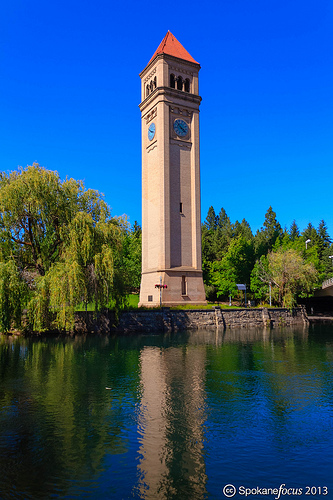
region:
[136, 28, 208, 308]
stone clock tower next to water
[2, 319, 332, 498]
water next to clock tower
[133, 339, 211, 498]
reflection of the clock tower in the water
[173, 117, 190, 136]
clock face on clock tower showing time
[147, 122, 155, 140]
clock on clock tower showing time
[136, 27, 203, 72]
red roof of the clock tower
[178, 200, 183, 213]
small window in stone clock tower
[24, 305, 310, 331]
stone wall at the edge of the water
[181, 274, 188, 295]
small door in clock tower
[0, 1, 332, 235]
clear blue sky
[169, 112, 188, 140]
A clock on the tower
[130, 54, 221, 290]
A tower in front of the water.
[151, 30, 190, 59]
The roof of the tower.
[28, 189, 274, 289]
Trees behind the tower.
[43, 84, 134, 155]
The sky is clear and blue.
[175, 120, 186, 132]
The hands on the clock is black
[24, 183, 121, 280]
The trees are green.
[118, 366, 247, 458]
A reflection of the tower in the water.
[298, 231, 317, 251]
A light pole sticking through the trees.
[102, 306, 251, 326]
A stone wall by the tower.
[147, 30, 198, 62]
Red pointy roof on a tall thin tower.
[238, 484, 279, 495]
The word Spokane before the word focus.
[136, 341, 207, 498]
A tall brown tower reflection in the water.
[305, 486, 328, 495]
The year 2013.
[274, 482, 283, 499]
The white letter F in focus.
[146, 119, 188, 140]
Two clocks on the top of a tower.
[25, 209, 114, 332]
A green willow tree to the left of a tower.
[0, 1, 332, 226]
Bright blue sky all around a tower.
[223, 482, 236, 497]
A round white circle with CC inside.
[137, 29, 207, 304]
A brown tower with red roof and two clocks.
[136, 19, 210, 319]
clock tower on side of river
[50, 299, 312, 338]
retaining wall on side of river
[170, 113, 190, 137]
clock on clock tower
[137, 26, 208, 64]
roof on clock tower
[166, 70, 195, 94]
arches on clock tower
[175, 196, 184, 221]
small window on clock tower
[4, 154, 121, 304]
trees next to clock tower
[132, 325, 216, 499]
reflection on water of clock tower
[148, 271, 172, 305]
lamp on side of river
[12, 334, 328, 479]
River running next to clock tower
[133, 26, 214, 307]
tall tan tower with clay red roof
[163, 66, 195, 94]
three arched windows at top of tan tower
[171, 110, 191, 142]
black and white clock at top of tan tower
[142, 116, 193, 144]
two black and white clocks on two sides of tan tower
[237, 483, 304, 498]
name in white letters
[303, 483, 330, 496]
year photo was take in white numbers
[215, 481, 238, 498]
cc symbol in white letters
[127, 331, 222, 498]
reflection of tan tower on surface of body of water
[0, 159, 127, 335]
weeping willow at water's edge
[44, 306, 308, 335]
raised rock foundation under tower